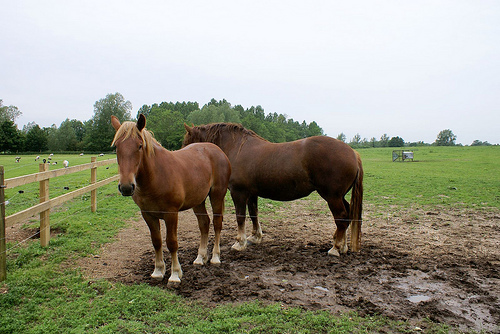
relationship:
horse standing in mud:
[110, 114, 231, 287] [131, 235, 498, 333]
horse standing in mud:
[180, 122, 363, 257] [131, 235, 498, 333]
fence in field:
[0, 156, 119, 282] [0, 145, 499, 333]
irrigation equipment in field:
[392, 149, 414, 163] [0, 145, 499, 333]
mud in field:
[131, 235, 498, 333] [0, 145, 499, 333]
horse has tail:
[180, 122, 363, 257] [349, 149, 364, 253]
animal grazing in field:
[62, 159, 68, 168] [0, 145, 499, 333]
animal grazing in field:
[79, 152, 84, 157] [0, 145, 499, 333]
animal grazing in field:
[13, 156, 22, 162] [0, 145, 499, 333]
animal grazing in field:
[33, 155, 39, 162] [0, 145, 499, 333]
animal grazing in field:
[49, 152, 54, 157] [0, 145, 499, 333]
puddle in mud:
[406, 295, 429, 304] [131, 235, 498, 333]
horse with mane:
[110, 114, 231, 287] [111, 120, 161, 159]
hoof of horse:
[166, 279, 182, 290] [110, 114, 231, 287]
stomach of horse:
[180, 181, 211, 210] [110, 114, 231, 287]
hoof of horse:
[150, 275, 164, 283] [110, 114, 231, 287]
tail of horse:
[349, 149, 364, 253] [180, 122, 363, 257]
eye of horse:
[113, 144, 117, 152] [110, 114, 231, 287]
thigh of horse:
[140, 210, 160, 232] [110, 114, 231, 287]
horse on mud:
[110, 114, 231, 287] [131, 235, 498, 333]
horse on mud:
[180, 122, 363, 257] [131, 235, 498, 333]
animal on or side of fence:
[79, 152, 84, 157] [0, 156, 119, 282]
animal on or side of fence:
[62, 159, 68, 168] [0, 156, 119, 282]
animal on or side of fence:
[49, 152, 54, 157] [0, 156, 119, 282]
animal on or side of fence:
[33, 155, 39, 162] [0, 156, 119, 282]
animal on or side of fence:
[13, 156, 22, 162] [0, 156, 119, 282]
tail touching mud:
[349, 149, 364, 253] [131, 235, 498, 333]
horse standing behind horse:
[180, 122, 363, 257] [110, 114, 231, 287]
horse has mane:
[110, 114, 231, 287] [111, 120, 161, 159]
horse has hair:
[180, 122, 363, 257] [181, 123, 267, 157]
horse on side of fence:
[110, 114, 231, 287] [0, 156, 119, 282]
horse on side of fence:
[180, 122, 363, 257] [0, 156, 119, 282]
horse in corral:
[180, 122, 363, 257] [62, 195, 499, 333]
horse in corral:
[110, 114, 231, 287] [62, 195, 499, 333]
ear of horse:
[136, 114, 147, 132] [110, 114, 231, 287]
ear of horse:
[109, 116, 121, 132] [110, 114, 231, 287]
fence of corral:
[0, 156, 119, 282] [62, 195, 499, 333]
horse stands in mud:
[110, 114, 231, 287] [131, 235, 498, 333]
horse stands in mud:
[180, 122, 363, 257] [131, 235, 498, 333]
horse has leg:
[110, 114, 231, 287] [164, 212, 184, 282]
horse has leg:
[110, 114, 231, 287] [139, 210, 166, 286]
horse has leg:
[110, 114, 231, 287] [209, 187, 225, 264]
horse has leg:
[110, 114, 231, 287] [192, 199, 210, 265]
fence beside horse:
[0, 156, 119, 282] [110, 114, 231, 287]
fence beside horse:
[0, 156, 119, 282] [180, 122, 363, 257]